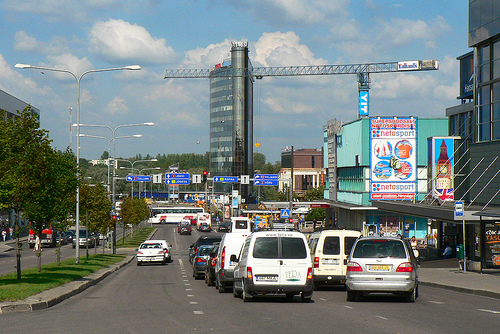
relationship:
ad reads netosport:
[369, 114, 418, 205] [381, 129, 416, 138]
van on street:
[348, 237, 421, 302] [2, 221, 499, 334]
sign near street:
[126, 176, 151, 182] [2, 221, 499, 334]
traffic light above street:
[202, 170, 211, 185] [2, 221, 499, 334]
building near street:
[323, 116, 450, 264] [2, 221, 499, 334]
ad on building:
[369, 114, 418, 205] [323, 116, 450, 264]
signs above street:
[124, 172, 280, 187] [2, 221, 499, 334]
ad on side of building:
[369, 114, 418, 205] [323, 116, 450, 264]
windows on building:
[325, 167, 365, 190] [323, 116, 450, 264]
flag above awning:
[426, 186, 455, 204] [372, 198, 500, 221]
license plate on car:
[149, 257, 156, 262] [138, 241, 167, 265]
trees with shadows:
[1, 102, 155, 280] [2, 253, 122, 288]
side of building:
[205, 68, 231, 198] [205, 42, 253, 205]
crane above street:
[164, 59, 438, 120] [2, 221, 499, 334]